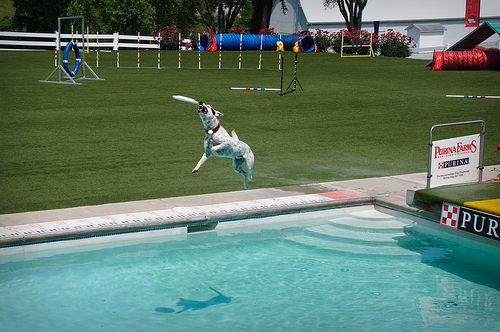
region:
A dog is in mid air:
[182, 85, 262, 195]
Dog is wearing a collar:
[200, 112, 225, 139]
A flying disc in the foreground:
[165, 85, 200, 110]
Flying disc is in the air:
[165, 81, 201, 111]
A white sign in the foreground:
[420, 115, 495, 195]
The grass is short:
[0, 40, 495, 215]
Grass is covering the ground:
[0, 41, 495, 221]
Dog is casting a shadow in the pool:
[145, 260, 240, 325]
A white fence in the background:
[1, 23, 168, 59]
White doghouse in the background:
[396, 14, 451, 60]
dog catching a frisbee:
[166, 80, 268, 187]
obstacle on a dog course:
[51, 15, 102, 97]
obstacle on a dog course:
[98, 33, 289, 71]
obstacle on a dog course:
[426, 42, 499, 76]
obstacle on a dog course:
[198, 25, 321, 58]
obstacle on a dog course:
[337, 29, 376, 61]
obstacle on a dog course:
[404, 15, 449, 57]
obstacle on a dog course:
[429, 44, 493, 79]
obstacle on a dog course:
[53, 10, 98, 89]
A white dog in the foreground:
[155, 86, 286, 196]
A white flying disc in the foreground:
[162, 81, 208, 121]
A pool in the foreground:
[0, 172, 495, 327]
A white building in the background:
[255, 0, 495, 55]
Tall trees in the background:
[2, 2, 272, 47]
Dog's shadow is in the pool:
[136, 281, 253, 321]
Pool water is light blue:
[0, 206, 496, 328]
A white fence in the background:
[1, 22, 196, 59]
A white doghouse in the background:
[395, 14, 457, 61]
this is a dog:
[193, 90, 256, 190]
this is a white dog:
[193, 97, 259, 187]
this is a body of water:
[19, 257, 97, 325]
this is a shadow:
[174, 288, 232, 316]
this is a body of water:
[286, 236, 437, 323]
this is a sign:
[422, 118, 489, 193]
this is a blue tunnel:
[196, 31, 316, 52]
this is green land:
[12, 114, 121, 186]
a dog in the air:
[198, 96, 255, 194]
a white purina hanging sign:
[425, 129, 489, 189]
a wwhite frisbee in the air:
[170, 89, 197, 113]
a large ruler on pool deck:
[1, 188, 364, 243]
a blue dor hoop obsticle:
[56, 17, 94, 85]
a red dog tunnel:
[423, 39, 492, 79]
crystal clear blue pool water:
[4, 195, 496, 330]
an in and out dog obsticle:
[81, 23, 288, 77]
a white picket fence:
[1, 22, 202, 57]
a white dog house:
[402, 16, 453, 58]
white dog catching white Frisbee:
[161, 80, 278, 191]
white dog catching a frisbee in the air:
[194, 97, 259, 189]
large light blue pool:
[8, 191, 495, 329]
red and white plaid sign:
[438, 200, 463, 232]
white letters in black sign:
[459, 207, 499, 240]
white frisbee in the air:
[172, 89, 198, 107]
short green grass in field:
[0, 57, 495, 210]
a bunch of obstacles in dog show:
[38, 18, 498, 95]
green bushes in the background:
[1, 1, 248, 41]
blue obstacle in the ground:
[196, 29, 317, 52]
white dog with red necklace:
[186, 98, 259, 183]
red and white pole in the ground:
[276, 33, 286, 70]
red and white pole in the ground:
[256, 32, 264, 68]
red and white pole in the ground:
[235, 32, 243, 65]